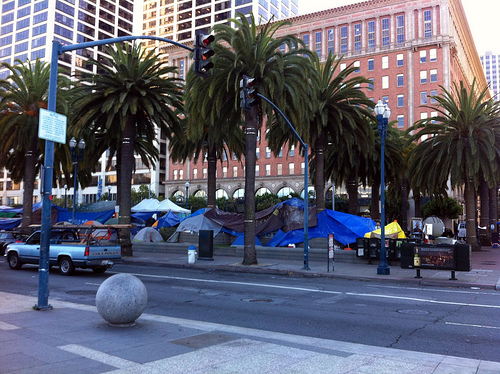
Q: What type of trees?
A: Palm.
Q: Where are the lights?
A: Over street.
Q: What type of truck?
A: Pick up.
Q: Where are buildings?
A: In city.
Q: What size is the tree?
A: Large.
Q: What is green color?
A: Tree.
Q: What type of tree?
A: Palm.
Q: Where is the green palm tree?
A: On the sidewalk.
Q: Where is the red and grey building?
A: Behind the palm trees.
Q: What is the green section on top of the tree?
A: The palms.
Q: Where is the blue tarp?
A: Under the palm tree.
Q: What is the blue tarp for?
A: To cover the objects.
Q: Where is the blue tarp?
A: Under the tree.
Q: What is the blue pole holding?
A: A light.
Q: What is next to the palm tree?
A: A blue pole.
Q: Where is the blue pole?
A: On the sidewalk.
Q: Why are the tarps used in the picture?
A: For protection of property.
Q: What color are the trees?
A: Green.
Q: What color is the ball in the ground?
A: Gray.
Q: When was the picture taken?
A: During the day.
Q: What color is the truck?
A: Blue.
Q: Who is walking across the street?
A: No one.